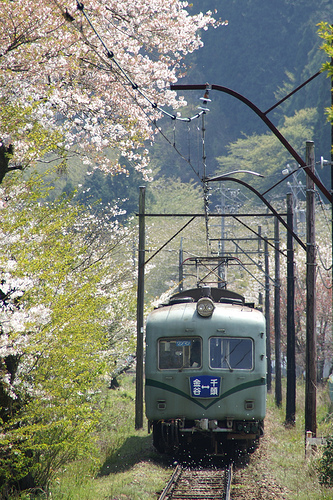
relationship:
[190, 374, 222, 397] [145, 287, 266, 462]
sign on car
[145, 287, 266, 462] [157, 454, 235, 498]
car on track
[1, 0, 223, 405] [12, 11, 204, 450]
cherry blossoms on tree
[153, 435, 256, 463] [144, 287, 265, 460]
wheels on car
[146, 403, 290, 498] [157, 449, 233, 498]
gravel on train tracks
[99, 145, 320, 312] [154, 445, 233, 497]
poles on sides of train tracks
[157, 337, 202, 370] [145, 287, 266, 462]
window on car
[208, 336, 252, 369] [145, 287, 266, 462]
window on car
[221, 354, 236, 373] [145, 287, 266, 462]
windshield wiper on car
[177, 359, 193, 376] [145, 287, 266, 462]
windshield wiper on car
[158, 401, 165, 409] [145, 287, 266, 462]
head light on car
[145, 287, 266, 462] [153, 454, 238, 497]
car on train track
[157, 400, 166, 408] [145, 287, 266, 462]
head light on car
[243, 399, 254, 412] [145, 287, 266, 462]
light on car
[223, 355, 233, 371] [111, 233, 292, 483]
windshield wiper on train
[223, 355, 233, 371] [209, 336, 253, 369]
windshield wiper on window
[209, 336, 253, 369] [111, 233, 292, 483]
window on train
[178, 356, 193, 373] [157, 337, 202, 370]
windshield wiper on window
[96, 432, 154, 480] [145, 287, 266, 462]
shadow from car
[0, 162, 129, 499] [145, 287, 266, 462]
bushes near car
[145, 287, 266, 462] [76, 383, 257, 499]
car on tracks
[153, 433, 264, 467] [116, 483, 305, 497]
petals falling on ground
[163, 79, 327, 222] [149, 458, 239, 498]
poles along train tracks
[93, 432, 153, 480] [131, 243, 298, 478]
shadow from train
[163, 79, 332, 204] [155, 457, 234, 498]
poles run along train track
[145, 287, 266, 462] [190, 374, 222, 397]
car with sign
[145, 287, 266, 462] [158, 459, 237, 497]
car on tracks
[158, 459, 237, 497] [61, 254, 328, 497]
tracks on ground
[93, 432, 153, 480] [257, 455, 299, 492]
shadow on ground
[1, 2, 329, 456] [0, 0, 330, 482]
cherry blossoms in trees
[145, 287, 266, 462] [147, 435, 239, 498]
car on tracks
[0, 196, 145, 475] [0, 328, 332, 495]
bushes in field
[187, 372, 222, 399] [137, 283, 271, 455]
sign on train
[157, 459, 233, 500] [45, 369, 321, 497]
tracks through meadow